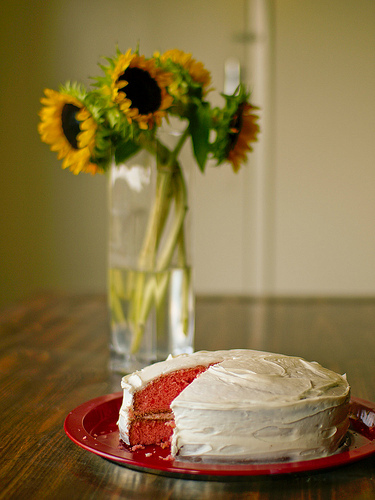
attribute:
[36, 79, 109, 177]
sunflower — small, yellow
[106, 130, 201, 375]
vase — clear, glass, filled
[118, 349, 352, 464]
cake — red, velvet, small, white, frosted, pink, carrot cake, covered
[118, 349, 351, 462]
icing — white, creamy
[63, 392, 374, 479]
plate — dark red, red, pie plate, round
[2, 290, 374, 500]
table — dark brown, wooden, large, brown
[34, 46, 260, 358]
sunflowers — bunched together, cut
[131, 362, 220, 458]
interior — red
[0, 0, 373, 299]
wall — white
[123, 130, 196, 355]
stem — long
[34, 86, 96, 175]
petals — yellow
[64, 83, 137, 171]
leaves — green